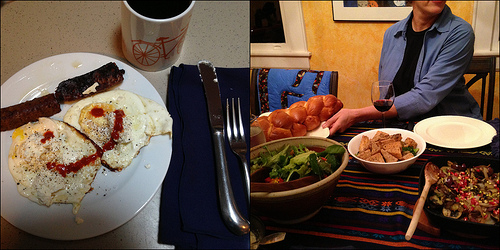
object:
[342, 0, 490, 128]
woman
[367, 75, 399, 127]
cup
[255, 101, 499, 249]
table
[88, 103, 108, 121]
red sauce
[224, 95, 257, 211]
fork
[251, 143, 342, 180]
green salad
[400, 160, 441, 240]
utensil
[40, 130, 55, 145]
eye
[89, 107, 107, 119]
eye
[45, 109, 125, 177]
smile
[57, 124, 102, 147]
pepper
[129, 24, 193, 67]
red bike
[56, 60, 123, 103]
sausage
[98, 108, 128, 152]
red sauce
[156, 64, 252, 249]
blue napkin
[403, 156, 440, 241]
wooden spoon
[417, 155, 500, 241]
black tray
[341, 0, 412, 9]
art work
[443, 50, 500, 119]
wooden chair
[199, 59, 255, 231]
butter knife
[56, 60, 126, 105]
sausage link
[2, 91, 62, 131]
sausage link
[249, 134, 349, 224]
bowl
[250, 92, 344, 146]
bread loaf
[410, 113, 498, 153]
dinner plate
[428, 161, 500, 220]
dinner entree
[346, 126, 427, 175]
bowl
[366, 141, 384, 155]
bread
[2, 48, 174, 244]
plate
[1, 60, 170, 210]
food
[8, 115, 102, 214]
egg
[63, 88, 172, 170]
egg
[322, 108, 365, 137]
hand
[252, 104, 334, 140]
platter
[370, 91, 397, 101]
glass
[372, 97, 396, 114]
wine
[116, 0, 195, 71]
cup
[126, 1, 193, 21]
coffee